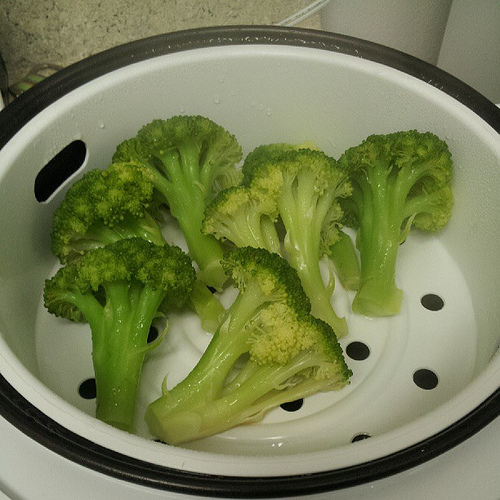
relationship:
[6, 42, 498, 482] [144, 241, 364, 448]
bowl with broccoli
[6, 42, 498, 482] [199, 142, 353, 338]
bowl with broccoli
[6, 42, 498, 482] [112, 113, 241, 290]
bowl with broccoli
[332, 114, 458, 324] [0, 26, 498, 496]
broccoli in steam bowl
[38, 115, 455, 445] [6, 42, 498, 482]
broccoli in bowl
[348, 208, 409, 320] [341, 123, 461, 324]
stem of broccoli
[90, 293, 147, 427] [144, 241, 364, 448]
stem piece of broccoli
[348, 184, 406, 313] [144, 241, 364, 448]
stem piece of broccoli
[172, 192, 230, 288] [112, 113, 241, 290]
stem piece of broccoli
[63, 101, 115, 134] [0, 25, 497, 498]
water drops on side of steamer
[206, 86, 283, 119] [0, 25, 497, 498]
water drops on side of steamer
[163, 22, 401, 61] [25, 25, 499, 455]
rim on steamer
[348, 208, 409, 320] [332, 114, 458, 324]
stem on broccoli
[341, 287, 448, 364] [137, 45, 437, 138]
steam holes in bottom of steamer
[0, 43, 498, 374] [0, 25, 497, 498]
coating on side of steamer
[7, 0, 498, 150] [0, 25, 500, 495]
reflection on vegetable steamer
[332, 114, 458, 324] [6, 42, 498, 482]
broccoli in bowl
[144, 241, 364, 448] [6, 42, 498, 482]
broccoli in bowl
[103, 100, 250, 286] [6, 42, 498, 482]
broccoli in bowl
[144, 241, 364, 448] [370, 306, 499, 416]
broccoli in bowl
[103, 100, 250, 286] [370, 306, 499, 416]
broccoli in bowl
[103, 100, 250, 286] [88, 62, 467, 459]
broccoli in bowl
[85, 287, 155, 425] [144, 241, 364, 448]
stem of broccoli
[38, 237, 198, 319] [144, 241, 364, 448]
head piece of broccoli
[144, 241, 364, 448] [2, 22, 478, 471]
broccoli in bowl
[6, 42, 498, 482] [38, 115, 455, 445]
bowl with broccoli